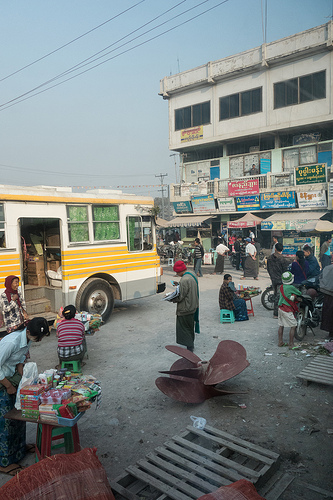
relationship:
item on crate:
[189, 414, 207, 430] [107, 420, 280, 498]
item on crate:
[190, 413, 207, 430] [134, 391, 306, 490]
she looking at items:
[0, 317, 53, 467] [14, 363, 107, 430]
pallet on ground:
[144, 436, 210, 476] [16, 230, 318, 497]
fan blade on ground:
[154, 338, 251, 406] [29, 264, 331, 497]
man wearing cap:
[161, 258, 201, 357] [171, 258, 189, 274]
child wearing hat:
[275, 271, 302, 350] [280, 269, 295, 285]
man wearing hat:
[162, 257, 200, 355] [172, 257, 185, 270]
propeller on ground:
[142, 327, 255, 405] [29, 264, 331, 497]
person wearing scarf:
[0, 274, 27, 329] [2, 286, 23, 302]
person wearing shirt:
[0, 274, 27, 329] [0, 289, 29, 337]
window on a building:
[159, 94, 217, 136] [157, 20, 331, 270]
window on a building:
[211, 80, 265, 122] [157, 20, 331, 270]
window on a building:
[263, 63, 331, 113] [157, 20, 331, 270]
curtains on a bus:
[87, 203, 125, 243] [3, 174, 169, 330]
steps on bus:
[20, 280, 60, 322] [3, 174, 169, 330]